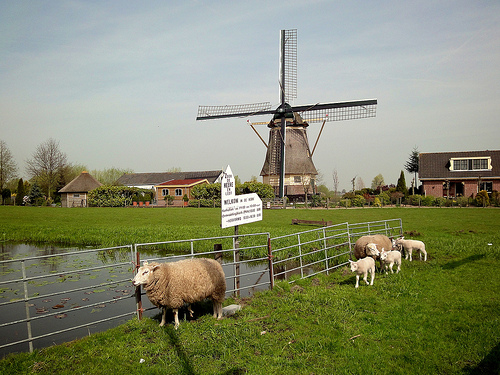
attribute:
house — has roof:
[419, 145, 498, 207]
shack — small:
[57, 169, 107, 211]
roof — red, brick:
[156, 179, 208, 190]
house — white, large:
[111, 161, 232, 206]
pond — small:
[19, 226, 92, 319]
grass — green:
[233, 283, 497, 373]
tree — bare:
[31, 138, 71, 206]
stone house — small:
[155, 170, 227, 218]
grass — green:
[1, 204, 498, 371]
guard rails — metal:
[233, 232, 275, 297]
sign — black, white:
[210, 163, 266, 234]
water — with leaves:
[7, 238, 244, 320]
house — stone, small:
[414, 152, 499, 199]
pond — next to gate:
[11, 187, 150, 371]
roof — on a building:
[151, 172, 206, 188]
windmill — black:
[193, 24, 378, 201]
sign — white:
[221, 164, 263, 229]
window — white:
[451, 153, 496, 175]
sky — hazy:
[5, 9, 498, 191]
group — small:
[348, 232, 425, 285]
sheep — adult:
[128, 257, 228, 328]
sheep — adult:
[354, 230, 395, 261]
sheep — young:
[344, 256, 373, 286]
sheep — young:
[375, 247, 405, 274]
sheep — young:
[396, 235, 426, 260]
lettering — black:
[221, 196, 261, 218]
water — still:
[4, 243, 277, 355]